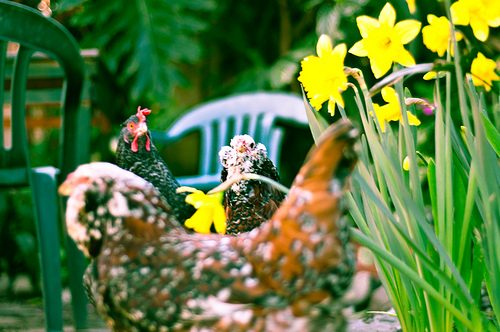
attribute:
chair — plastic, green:
[3, 3, 95, 329]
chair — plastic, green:
[149, 91, 331, 203]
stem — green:
[386, 74, 424, 226]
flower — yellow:
[339, 16, 437, 61]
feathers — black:
[153, 160, 166, 185]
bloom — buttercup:
[297, 32, 349, 116]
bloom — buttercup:
[469, 50, 499, 93]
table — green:
[1, 43, 138, 330]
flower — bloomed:
[294, 32, 350, 116]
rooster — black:
[117, 106, 287, 238]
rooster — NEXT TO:
[221, 132, 278, 221]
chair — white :
[147, 92, 334, 189]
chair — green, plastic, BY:
[0, 0, 85, 330]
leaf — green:
[411, 120, 471, 213]